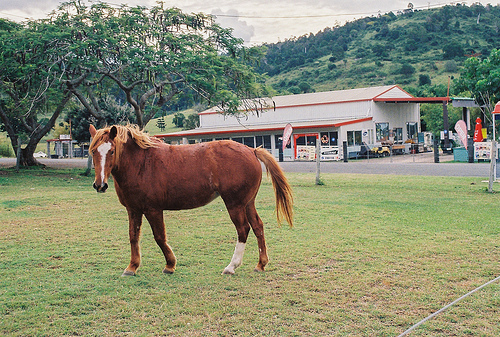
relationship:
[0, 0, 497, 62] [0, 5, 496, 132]
skies over hills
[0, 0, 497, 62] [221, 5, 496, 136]
skies over trees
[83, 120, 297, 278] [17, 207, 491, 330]
brown horse standing on grass